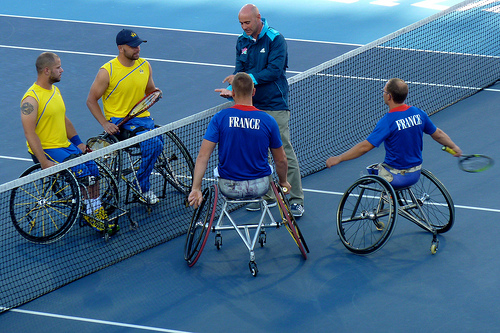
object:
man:
[16, 48, 122, 234]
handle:
[440, 145, 459, 157]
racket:
[440, 144, 497, 174]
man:
[211, 1, 307, 220]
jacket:
[224, 16, 293, 111]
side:
[185, 182, 207, 211]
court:
[0, 0, 500, 333]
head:
[230, 71, 256, 105]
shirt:
[20, 80, 72, 155]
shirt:
[99, 55, 151, 120]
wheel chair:
[181, 162, 314, 278]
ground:
[0, 0, 500, 333]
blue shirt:
[365, 102, 439, 171]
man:
[186, 70, 293, 210]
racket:
[98, 88, 163, 140]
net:
[0, 0, 500, 315]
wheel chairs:
[333, 167, 459, 257]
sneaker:
[79, 206, 107, 232]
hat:
[114, 27, 149, 49]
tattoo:
[20, 101, 35, 116]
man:
[324, 75, 463, 191]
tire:
[182, 181, 219, 269]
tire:
[266, 172, 311, 261]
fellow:
[16, 50, 122, 233]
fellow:
[85, 27, 164, 205]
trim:
[229, 103, 262, 112]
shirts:
[202, 104, 285, 182]